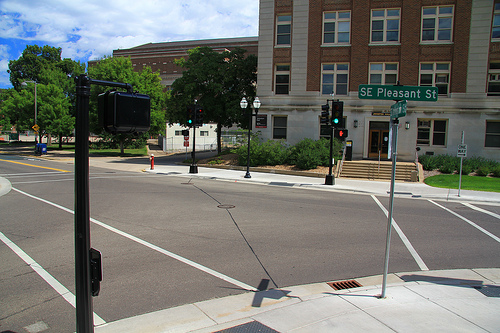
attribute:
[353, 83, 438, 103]
street sign — green, white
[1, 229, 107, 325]
line — white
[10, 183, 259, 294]
line — white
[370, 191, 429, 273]
line — white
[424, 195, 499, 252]
line — white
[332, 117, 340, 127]
traffic light — green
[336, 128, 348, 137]
pedestrian signal — red, lit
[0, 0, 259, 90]
clouds — white, bright, big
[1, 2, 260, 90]
sky — blue, cloudy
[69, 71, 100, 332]
pole — black, short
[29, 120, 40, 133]
sign — yellow, black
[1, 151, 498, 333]
road — empty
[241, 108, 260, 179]
lamp post — black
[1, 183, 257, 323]
crosswalk — white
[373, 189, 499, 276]
crosswalk — white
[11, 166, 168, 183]
crosswalk — white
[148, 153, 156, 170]
fire hydrant — red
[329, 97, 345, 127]
light fixture — black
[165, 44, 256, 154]
tree — green, tall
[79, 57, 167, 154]
tree — green, tall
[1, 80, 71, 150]
tree — green, tall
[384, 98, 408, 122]
street sign — green, white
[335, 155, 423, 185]
steps — tan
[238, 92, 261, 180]
street light — white, black, small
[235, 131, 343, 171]
bushes — green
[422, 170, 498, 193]
grass — green